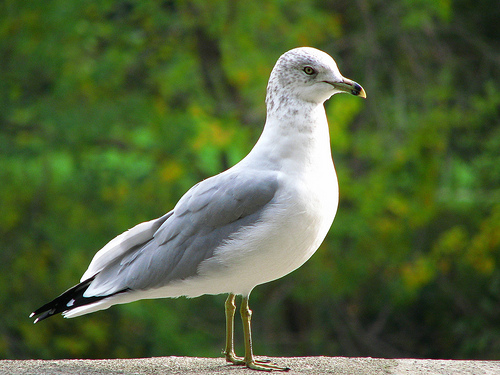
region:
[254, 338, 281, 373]
right foot of bird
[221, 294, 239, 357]
left leg of bird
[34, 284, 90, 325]
black tip of bird's tail feathers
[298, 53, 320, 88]
bird's right eye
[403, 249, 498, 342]
greenery in lower right portion of photo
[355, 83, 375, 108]
yellow tip of beak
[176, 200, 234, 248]
grey colored feathers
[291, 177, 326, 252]
white feathers on the bird's breast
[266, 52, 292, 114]
grey and white feathers on bird's head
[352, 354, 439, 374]
grey cement under bird's feet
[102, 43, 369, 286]
gray black and white bird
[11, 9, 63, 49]
dark green and light green leaves on trees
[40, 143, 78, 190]
dark green and light green leaves on trees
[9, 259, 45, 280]
dark green and light green leaves on trees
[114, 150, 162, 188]
dark green and light green leaves on trees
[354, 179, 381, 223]
dark green and light green leaves on trees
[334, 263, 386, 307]
dark green and light green leaves on trees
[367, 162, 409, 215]
dark green and light green leaves on trees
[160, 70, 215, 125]
dark green and light green leaves on trees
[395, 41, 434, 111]
dark green and light green leaves on trees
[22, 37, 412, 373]
a bird sitting on the ground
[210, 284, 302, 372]
bird claws on the ledge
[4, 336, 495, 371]
the ledge is concrete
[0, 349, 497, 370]
the ledge is grey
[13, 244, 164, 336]
the tailfeathers are black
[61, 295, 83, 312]
a blue spot on the tailfeathers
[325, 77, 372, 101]
the bird's beak is dark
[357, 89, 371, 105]
the beak tip is orange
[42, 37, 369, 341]
the bird's feathers are white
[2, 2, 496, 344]
green trees behind the bird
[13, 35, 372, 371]
the white and grey bird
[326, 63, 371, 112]
the beak of the bird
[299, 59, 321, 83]
the eye of the bird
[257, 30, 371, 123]
the head of the bird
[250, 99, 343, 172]
the neck of the bird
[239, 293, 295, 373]
the right leg of the bird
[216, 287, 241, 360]
the left leg of the bird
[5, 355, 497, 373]
the cement surface that the bird is on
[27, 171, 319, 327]
the wing of the bird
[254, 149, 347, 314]
the chest of the bird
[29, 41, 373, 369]
a black grey and yellow seagull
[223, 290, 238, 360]
a yellow leg of a seagull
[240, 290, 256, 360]
a yellow leg of a seagull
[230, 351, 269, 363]
a yellow foot of a seagull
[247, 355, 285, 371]
a yellow foot of a seagull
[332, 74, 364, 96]
a yellow and black beak of a seagull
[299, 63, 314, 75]
a yellow and black eye of a seagull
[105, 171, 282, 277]
a grey seagull wing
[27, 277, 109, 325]
a black seagull tail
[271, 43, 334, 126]
a grey and white seagull head